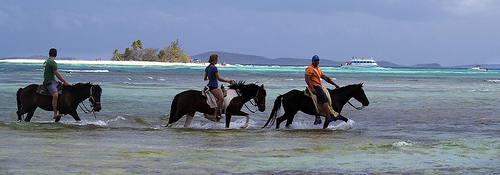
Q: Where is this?
A: This is at the ocean.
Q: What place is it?
A: It is an ocean.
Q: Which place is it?
A: It is an ocean.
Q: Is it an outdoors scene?
A: Yes, it is outdoors.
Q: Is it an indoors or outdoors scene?
A: It is outdoors.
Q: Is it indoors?
A: No, it is outdoors.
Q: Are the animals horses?
A: Yes, all the animals are horses.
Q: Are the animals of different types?
A: No, all the animals are horses.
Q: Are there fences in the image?
A: No, there are no fences.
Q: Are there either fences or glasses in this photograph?
A: No, there are no fences or glasses.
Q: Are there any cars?
A: No, there are no cars.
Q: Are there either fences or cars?
A: No, there are no cars or fences.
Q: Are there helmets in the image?
A: No, there are no helmets.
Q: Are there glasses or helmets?
A: No, there are no helmets or glasses.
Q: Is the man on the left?
A: Yes, the man is on the left of the image.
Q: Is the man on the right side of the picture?
A: No, the man is on the left of the image.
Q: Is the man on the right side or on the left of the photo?
A: The man is on the left of the image.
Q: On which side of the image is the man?
A: The man is on the left of the image.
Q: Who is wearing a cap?
A: The man is wearing a cap.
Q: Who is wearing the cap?
A: The man is wearing a cap.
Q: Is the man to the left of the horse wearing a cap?
A: Yes, the man is wearing a cap.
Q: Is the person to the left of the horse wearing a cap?
A: Yes, the man is wearing a cap.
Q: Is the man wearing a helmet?
A: No, the man is wearing a cap.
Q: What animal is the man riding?
A: The man is riding a horse.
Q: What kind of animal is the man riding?
A: The man is riding a horse.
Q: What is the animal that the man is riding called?
A: The animal is a horse.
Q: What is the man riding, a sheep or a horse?
A: The man is riding a horse.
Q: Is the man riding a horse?
A: Yes, the man is riding a horse.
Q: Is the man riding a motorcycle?
A: No, the man is riding a horse.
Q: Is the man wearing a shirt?
A: Yes, the man is wearing a shirt.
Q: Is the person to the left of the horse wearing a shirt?
A: Yes, the man is wearing a shirt.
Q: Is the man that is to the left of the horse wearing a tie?
A: No, the man is wearing a shirt.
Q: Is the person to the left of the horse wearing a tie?
A: No, the man is wearing a shirt.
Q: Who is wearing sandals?
A: The man is wearing sandals.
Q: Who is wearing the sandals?
A: The man is wearing sandals.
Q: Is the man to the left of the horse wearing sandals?
A: Yes, the man is wearing sandals.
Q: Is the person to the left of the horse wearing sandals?
A: Yes, the man is wearing sandals.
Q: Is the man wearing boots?
A: No, the man is wearing sandals.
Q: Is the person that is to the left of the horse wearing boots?
A: No, the man is wearing sandals.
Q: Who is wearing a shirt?
A: The man is wearing a shirt.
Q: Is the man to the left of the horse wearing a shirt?
A: Yes, the man is wearing a shirt.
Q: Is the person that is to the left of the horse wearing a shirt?
A: Yes, the man is wearing a shirt.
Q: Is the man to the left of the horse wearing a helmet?
A: No, the man is wearing a shirt.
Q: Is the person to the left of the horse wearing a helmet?
A: No, the man is wearing a shirt.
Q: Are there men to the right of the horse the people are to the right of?
A: No, the man is to the left of the horse.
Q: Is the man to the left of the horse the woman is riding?
A: Yes, the man is to the left of the horse.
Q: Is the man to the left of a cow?
A: No, the man is to the left of the horse.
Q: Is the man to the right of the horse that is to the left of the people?
A: No, the man is to the left of the horse.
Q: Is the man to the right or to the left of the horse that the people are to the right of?
A: The man is to the left of the horse.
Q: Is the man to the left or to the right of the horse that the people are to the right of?
A: The man is to the left of the horse.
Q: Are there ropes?
A: No, there are no ropes.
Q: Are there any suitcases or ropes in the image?
A: No, there are no ropes or suitcases.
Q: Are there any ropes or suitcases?
A: No, there are no ropes or suitcases.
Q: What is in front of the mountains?
A: The water is in front of the mountains.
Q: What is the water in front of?
A: The water is in front of the mountains.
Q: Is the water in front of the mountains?
A: Yes, the water is in front of the mountains.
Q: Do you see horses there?
A: Yes, there are horses.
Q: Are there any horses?
A: Yes, there are horses.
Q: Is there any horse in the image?
A: Yes, there are horses.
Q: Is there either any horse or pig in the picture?
A: Yes, there are horses.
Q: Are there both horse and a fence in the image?
A: No, there are horses but no fences.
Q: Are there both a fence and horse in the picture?
A: No, there are horses but no fences.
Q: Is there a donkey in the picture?
A: No, there are no donkeys.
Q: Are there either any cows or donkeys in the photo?
A: No, there are no donkeys or cows.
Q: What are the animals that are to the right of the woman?
A: The animals are horses.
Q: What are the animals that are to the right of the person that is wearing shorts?
A: The animals are horses.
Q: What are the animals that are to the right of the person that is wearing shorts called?
A: The animals are horses.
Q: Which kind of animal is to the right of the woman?
A: The animals are horses.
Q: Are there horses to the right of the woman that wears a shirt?
A: Yes, there are horses to the right of the woman.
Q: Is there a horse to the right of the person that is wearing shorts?
A: Yes, there are horses to the right of the woman.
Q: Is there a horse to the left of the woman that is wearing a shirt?
A: No, the horses are to the right of the woman.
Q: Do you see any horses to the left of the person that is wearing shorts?
A: No, the horses are to the right of the woman.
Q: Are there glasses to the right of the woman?
A: No, there are horses to the right of the woman.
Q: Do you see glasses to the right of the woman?
A: No, there are horses to the right of the woman.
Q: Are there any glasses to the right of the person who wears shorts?
A: No, there are horses to the right of the woman.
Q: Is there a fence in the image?
A: No, there are no fences.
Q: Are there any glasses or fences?
A: No, there are no fences or glasses.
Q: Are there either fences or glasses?
A: No, there are no fences or glasses.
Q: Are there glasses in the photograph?
A: No, there are no glasses.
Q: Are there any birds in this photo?
A: No, there are no birds.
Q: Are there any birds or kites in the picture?
A: No, there are no birds or kites.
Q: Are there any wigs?
A: No, there are no wigs.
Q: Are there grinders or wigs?
A: No, there are no wigs or grinders.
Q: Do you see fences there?
A: No, there are no fences.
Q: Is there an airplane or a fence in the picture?
A: No, there are no fences or airplanes.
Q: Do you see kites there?
A: No, there are no kites.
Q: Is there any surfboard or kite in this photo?
A: No, there are no kites or surfboards.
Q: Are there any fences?
A: No, there are no fences.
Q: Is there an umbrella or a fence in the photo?
A: No, there are no fences or umbrellas.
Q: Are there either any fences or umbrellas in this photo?
A: No, there are no fences or umbrellas.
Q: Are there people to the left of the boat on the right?
A: Yes, there are people to the left of the boat.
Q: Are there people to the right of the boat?
A: No, the people are to the left of the boat.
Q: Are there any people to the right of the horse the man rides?
A: Yes, there are people to the right of the horse.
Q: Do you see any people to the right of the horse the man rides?
A: Yes, there are people to the right of the horse.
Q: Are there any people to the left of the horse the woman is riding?
A: No, the people are to the right of the horse.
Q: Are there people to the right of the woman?
A: Yes, there are people to the right of the woman.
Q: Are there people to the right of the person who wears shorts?
A: Yes, there are people to the right of the woman.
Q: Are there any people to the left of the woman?
A: No, the people are to the right of the woman.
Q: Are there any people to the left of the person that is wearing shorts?
A: No, the people are to the right of the woman.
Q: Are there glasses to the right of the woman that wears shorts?
A: No, there are people to the right of the woman.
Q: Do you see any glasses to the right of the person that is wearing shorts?
A: No, there are people to the right of the woman.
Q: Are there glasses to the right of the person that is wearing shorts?
A: No, there are people to the right of the woman.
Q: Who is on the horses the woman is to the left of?
A: The people are on the horses.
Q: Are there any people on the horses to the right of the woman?
A: Yes, there are people on the horses.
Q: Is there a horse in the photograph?
A: Yes, there is a horse.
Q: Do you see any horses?
A: Yes, there is a horse.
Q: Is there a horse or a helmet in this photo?
A: Yes, there is a horse.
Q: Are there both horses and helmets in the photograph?
A: No, there is a horse but no helmets.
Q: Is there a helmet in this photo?
A: No, there are no helmets.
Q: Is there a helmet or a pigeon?
A: No, there are no helmets or pigeons.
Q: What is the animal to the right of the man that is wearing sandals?
A: The animal is a horse.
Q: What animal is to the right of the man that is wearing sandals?
A: The animal is a horse.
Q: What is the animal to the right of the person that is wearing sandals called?
A: The animal is a horse.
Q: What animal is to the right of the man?
A: The animal is a horse.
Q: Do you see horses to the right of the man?
A: Yes, there is a horse to the right of the man.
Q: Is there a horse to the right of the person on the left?
A: Yes, there is a horse to the right of the man.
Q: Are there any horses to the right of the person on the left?
A: Yes, there is a horse to the right of the man.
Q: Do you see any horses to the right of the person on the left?
A: Yes, there is a horse to the right of the man.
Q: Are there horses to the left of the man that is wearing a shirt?
A: No, the horse is to the right of the man.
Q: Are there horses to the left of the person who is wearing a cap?
A: No, the horse is to the right of the man.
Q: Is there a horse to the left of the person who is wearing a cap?
A: No, the horse is to the right of the man.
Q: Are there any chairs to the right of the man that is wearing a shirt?
A: No, there is a horse to the right of the man.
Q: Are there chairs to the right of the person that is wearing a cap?
A: No, there is a horse to the right of the man.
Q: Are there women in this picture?
A: Yes, there is a woman.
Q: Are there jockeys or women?
A: Yes, there is a woman.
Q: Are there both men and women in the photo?
A: Yes, there are both a woman and a man.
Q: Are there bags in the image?
A: No, there are no bags.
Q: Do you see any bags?
A: No, there are no bags.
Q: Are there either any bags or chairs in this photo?
A: No, there are no bags or chairs.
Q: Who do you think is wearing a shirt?
A: The woman is wearing a shirt.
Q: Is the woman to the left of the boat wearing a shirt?
A: Yes, the woman is wearing a shirt.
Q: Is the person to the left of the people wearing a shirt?
A: Yes, the woman is wearing a shirt.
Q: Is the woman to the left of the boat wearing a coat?
A: No, the woman is wearing a shirt.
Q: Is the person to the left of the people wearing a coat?
A: No, the woman is wearing a shirt.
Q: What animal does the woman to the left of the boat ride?
A: The woman rides a horse.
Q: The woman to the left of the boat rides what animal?
A: The woman rides a horse.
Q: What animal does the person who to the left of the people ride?
A: The woman rides a horse.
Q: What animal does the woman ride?
A: The woman rides a horse.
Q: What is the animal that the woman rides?
A: The animal is a horse.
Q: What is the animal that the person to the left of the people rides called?
A: The animal is a horse.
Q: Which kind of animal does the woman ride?
A: The woman rides a horse.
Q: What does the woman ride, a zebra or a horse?
A: The woman rides a horse.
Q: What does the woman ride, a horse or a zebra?
A: The woman rides a horse.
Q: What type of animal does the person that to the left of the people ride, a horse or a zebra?
A: The woman rides a horse.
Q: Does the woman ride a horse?
A: Yes, the woman rides a horse.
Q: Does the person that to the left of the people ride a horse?
A: Yes, the woman rides a horse.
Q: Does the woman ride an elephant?
A: No, the woman rides a horse.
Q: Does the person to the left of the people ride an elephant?
A: No, the woman rides a horse.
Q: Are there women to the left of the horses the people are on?
A: Yes, there is a woman to the left of the horses.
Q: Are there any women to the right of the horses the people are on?
A: No, the woman is to the left of the horses.